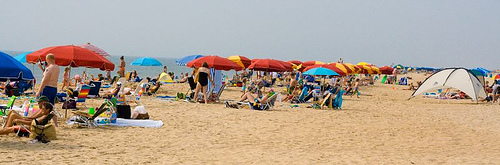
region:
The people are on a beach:
[0, 31, 490, 147]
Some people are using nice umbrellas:
[20, 16, 488, 144]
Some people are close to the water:
[16, 30, 486, 163]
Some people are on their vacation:
[26, 8, 486, 156]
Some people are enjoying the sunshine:
[1, 7, 492, 152]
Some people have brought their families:
[3, 18, 491, 143]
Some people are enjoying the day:
[22, 20, 487, 147]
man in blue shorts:
[37, 54, 67, 101]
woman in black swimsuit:
[189, 60, 213, 97]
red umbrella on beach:
[248, 56, 293, 74]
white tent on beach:
[411, 66, 484, 108]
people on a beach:
[0, 26, 499, 153]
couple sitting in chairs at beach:
[1, 94, 67, 149]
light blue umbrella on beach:
[129, 54, 164, 69]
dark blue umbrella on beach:
[0, 43, 34, 88]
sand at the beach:
[181, 118, 481, 161]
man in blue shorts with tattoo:
[35, 54, 63, 103]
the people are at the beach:
[1, 63, 498, 139]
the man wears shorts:
[41, 88, 56, 108]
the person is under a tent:
[408, 70, 486, 102]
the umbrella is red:
[25, 45, 112, 72]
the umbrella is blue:
[134, 53, 161, 65]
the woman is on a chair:
[8, 108, 56, 138]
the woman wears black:
[198, 71, 209, 84]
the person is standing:
[119, 50, 126, 76]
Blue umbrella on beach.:
[309, 63, 334, 78]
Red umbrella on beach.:
[251, 58, 281, 72]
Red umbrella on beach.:
[191, 55, 254, 84]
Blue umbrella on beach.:
[135, 55, 176, 63]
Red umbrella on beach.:
[47, 47, 105, 72]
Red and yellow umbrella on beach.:
[335, 57, 355, 83]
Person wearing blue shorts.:
[40, 83, 65, 100]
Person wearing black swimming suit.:
[192, 70, 214, 85]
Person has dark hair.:
[38, 101, 53, 115]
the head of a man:
[41, 49, 66, 71]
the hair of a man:
[41, 53, 66, 67]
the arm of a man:
[34, 69, 55, 98]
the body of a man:
[29, 52, 66, 112]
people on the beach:
[51, 37, 223, 132]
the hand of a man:
[29, 77, 51, 97]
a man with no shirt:
[26, 68, 77, 101]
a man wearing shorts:
[32, 82, 64, 104]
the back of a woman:
[180, 39, 233, 104]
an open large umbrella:
[312, 67, 344, 97]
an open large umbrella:
[254, 52, 277, 84]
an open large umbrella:
[201, 49, 224, 79]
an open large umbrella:
[135, 41, 177, 86]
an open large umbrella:
[29, 28, 98, 88]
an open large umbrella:
[347, 76, 364, 86]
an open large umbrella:
[354, 52, 379, 82]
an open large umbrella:
[320, 56, 347, 83]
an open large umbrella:
[378, 58, 398, 82]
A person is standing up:
[36, 53, 61, 128]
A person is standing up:
[118, 55, 127, 77]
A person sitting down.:
[3, 103, 53, 137]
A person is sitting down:
[3, 96, 45, 123]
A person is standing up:
[193, 62, 214, 104]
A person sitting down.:
[236, 90, 278, 110]